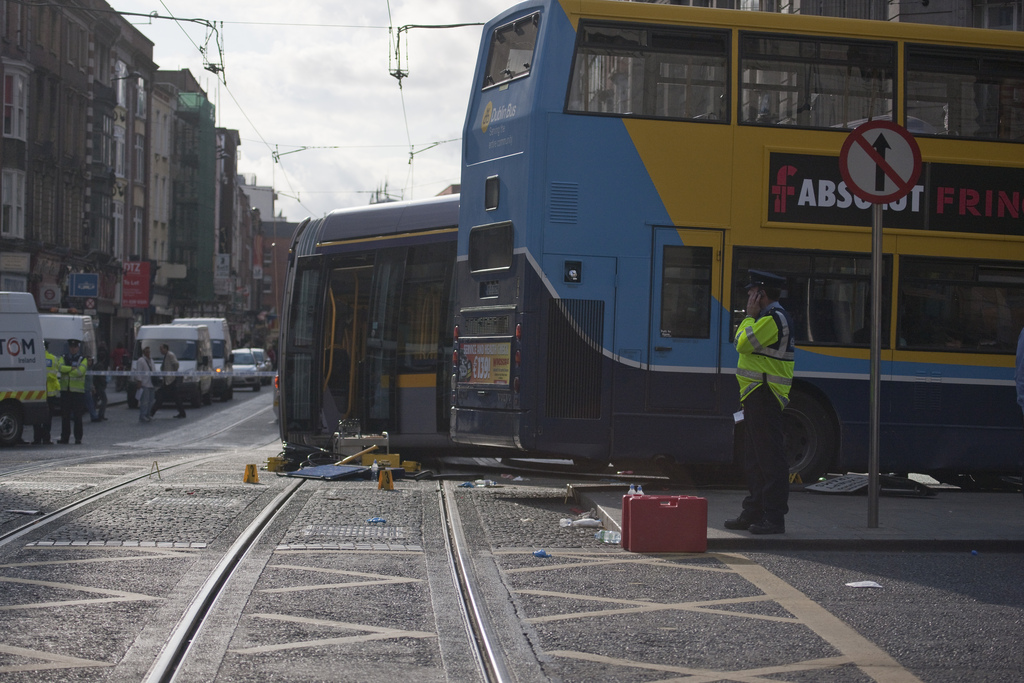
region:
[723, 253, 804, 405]
yellow safety vest worn by man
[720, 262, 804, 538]
man talking on cell phone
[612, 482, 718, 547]
red box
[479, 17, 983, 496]
blue and yellow double deck bus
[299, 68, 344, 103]
white clouds in blue sky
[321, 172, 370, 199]
white clouds in blue sky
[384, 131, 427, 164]
white clouds in blue sky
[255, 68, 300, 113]
white clouds in blue sky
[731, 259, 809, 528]
a crossing guard holding a cell phone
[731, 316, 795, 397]
a bright green safety vest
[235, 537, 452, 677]
marking criscrossing on the street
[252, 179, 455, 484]
a large bus over-turned on the street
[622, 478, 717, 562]
a large red plastic case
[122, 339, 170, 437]
a man watching the accident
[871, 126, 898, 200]
a black arrow on a sign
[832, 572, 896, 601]
a white paper laying on the street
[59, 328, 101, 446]
a policeman standing behind a van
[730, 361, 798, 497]
A person eating a orange.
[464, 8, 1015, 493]
yellow and blue double deck bus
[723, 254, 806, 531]
man standing by bus stop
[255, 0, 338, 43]
white clouds in blue sky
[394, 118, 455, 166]
white clouds in blue sky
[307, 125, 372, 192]
white clouds in blue sky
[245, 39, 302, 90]
white clouds in blue sky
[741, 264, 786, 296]
Black police hat on a head.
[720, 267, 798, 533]
Policeman in a yellow coat and black hat.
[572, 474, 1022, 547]
Sidewalk a policeman is on.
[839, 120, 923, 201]
Round sign with red circle and black arrow pointing up.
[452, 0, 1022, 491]
Blue and yellow double decker bus.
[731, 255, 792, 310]
the mans head above shoulders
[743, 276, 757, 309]
the facial area of the mans head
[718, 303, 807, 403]
the mans shirt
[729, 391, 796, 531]
the mans pants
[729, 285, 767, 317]
the mans hand at end of arm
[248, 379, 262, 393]
the vehicles front tire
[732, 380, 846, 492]
the vehicles rear tire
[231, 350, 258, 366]
the front windshield of the vehicle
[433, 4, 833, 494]
the rear part of the vehicle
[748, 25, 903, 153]
a window on the bus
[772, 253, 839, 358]
a window on the bus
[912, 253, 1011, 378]
a window on the bus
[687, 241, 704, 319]
a window on the bus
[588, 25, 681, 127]
a window on the bus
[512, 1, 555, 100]
a window on the bus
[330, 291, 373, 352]
a window on the bus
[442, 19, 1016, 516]
A large two story bus.